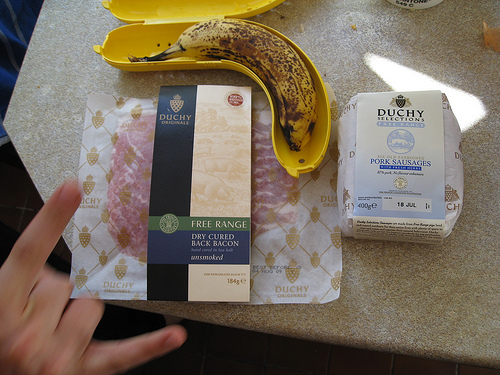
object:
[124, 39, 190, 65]
holder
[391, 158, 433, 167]
sausages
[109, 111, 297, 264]
bacon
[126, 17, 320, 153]
banana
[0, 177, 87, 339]
finger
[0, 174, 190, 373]
person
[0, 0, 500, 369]
countertop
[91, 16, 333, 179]
case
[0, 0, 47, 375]
floor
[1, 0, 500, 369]
table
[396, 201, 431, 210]
date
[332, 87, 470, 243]
package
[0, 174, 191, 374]
hand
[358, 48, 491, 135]
light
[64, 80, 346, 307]
package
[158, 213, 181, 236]
logo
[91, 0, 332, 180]
container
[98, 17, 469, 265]
food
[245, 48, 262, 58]
spots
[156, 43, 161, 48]
holes